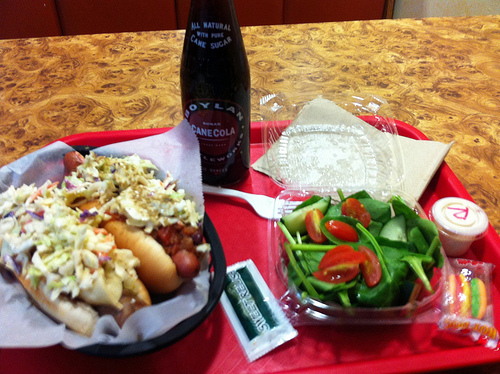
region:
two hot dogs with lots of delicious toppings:
[1, 139, 212, 336]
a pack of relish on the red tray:
[221, 255, 298, 369]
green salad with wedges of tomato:
[281, 186, 448, 321]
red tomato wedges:
[314, 243, 378, 283]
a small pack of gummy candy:
[445, 253, 498, 338]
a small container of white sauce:
[432, 196, 487, 251]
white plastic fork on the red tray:
[202, 182, 296, 218]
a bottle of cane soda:
[182, 1, 251, 184]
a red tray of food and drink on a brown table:
[3, 26, 492, 373]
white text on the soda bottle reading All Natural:
[189, 18, 233, 33]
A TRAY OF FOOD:
[5, 94, 493, 368]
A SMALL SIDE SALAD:
[261, 111, 472, 338]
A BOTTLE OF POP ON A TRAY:
[165, 4, 272, 189]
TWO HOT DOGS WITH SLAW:
[5, 141, 222, 341]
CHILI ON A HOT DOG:
[151, 205, 208, 281]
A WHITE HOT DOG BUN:
[62, 160, 216, 305]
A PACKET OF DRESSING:
[216, 254, 305, 370]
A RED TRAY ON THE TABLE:
[7, 91, 468, 371]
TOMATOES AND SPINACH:
[304, 208, 419, 303]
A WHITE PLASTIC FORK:
[177, 164, 305, 229]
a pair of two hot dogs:
[1, 150, 205, 335]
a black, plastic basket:
[0, 144, 227, 356]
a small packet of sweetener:
[220, 257, 297, 361]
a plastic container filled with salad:
[258, 87, 461, 326]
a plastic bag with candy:
[439, 257, 499, 335]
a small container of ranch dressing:
[429, 195, 489, 256]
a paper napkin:
[251, 94, 454, 207]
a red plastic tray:
[0, 115, 499, 372]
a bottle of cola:
[179, 2, 255, 187]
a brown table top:
[0, 17, 498, 236]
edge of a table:
[316, 20, 365, 26]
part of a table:
[425, 82, 467, 121]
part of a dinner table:
[64, 80, 128, 114]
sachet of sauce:
[249, 290, 271, 330]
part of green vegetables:
[350, 235, 398, 256]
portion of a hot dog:
[101, 190, 171, 248]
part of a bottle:
[211, 78, 230, 140]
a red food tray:
[227, 214, 249, 249]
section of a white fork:
[256, 202, 271, 206]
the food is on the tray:
[3, 85, 478, 372]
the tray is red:
[27, 99, 467, 367]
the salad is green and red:
[281, 187, 425, 308]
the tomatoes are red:
[298, 182, 380, 291]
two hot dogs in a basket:
[16, 132, 216, 366]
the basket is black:
[22, 114, 238, 334]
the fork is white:
[224, 170, 334, 243]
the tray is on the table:
[19, 71, 499, 366]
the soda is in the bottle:
[177, 5, 276, 207]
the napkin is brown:
[281, 92, 461, 237]